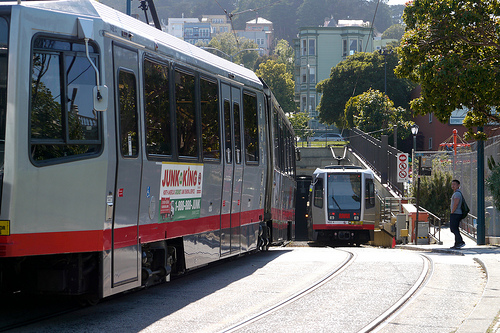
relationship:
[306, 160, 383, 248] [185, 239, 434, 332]
train on tracks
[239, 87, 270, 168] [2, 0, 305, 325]
windows on train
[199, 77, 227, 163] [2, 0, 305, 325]
windows on train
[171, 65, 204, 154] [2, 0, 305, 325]
windows on train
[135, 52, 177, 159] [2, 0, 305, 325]
windows on train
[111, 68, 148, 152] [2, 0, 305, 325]
windows on train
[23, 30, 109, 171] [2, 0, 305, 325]
windows on train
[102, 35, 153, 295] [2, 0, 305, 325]
door on train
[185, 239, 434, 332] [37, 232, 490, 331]
tracks on road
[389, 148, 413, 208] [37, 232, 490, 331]
signs on road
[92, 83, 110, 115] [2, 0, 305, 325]
mirror on train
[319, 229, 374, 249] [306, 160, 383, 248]
wheel on train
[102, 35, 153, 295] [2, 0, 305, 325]
door of train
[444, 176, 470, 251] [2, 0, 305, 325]
man watching train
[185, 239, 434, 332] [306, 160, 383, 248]
tracks for train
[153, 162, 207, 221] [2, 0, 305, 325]
advertisement on train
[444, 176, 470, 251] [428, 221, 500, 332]
man on sidewalk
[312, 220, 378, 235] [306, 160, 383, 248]
stripe on train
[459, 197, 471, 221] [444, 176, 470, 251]
backpack of man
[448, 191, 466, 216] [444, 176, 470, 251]
shirt of man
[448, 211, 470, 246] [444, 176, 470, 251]
pants of man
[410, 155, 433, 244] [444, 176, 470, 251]
post beside man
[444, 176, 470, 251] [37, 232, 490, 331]
man on side of road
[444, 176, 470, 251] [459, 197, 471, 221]
man has backpack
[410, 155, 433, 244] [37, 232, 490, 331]
post by road